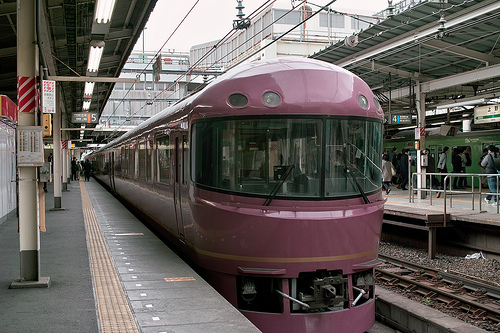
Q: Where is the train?
A: On the train track beside the platform.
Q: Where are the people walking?
A: On the platform.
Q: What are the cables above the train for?
A: Electrical inlet for the electric trains.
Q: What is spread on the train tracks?
A: Small stones.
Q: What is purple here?
A: The train.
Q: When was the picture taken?
A: In the day.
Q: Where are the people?
A: At the train station.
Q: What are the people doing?
A: Waiting for the train.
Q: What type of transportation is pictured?
A: A train.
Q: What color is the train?
A: Purple.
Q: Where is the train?
A: Train station.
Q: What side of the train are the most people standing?
A: The right.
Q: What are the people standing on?
A: A platform.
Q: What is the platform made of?
A: Concrete.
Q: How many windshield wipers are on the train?
A: 2.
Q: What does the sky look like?
A: Overcast.